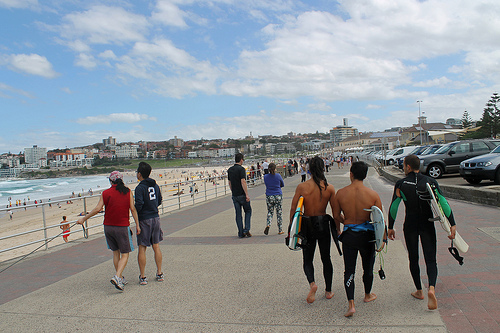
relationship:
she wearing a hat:
[75, 168, 144, 293] [105, 168, 125, 184]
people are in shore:
[2, 154, 307, 245] [1, 158, 288, 266]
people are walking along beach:
[2, 154, 307, 245] [1, 163, 281, 265]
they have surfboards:
[284, 154, 458, 318] [285, 181, 472, 258]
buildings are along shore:
[0, 141, 242, 175] [1, 158, 288, 266]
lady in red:
[75, 168, 144, 293] [102, 185, 133, 227]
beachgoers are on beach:
[2, 154, 307, 245] [1, 163, 281, 265]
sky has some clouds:
[1, 1, 497, 153] [230, 0, 498, 99]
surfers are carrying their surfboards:
[284, 154, 458, 318] [285, 181, 472, 258]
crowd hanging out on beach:
[2, 154, 307, 245] [1, 163, 281, 265]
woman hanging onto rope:
[75, 168, 144, 293] [3, 216, 77, 293]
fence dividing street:
[2, 147, 293, 279] [3, 159, 496, 332]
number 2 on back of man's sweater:
[147, 185, 159, 204] [137, 175, 164, 221]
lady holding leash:
[75, 168, 144, 293] [3, 216, 77, 293]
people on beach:
[2, 154, 307, 245] [1, 163, 281, 265]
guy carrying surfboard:
[380, 157, 460, 313] [422, 179, 473, 262]